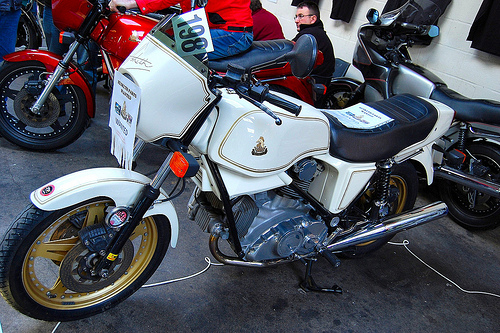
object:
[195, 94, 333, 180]
bars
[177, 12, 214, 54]
number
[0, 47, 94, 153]
wheel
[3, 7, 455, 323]
bike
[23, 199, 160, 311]
gold rim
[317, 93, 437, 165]
seat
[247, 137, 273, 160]
logo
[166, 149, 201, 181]
signal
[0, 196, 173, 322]
black tire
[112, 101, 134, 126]
graphic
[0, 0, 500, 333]
table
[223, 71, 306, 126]
handlebar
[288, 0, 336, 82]
man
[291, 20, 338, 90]
jacket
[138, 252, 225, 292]
cord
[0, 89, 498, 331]
ground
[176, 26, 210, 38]
9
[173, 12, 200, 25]
1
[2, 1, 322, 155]
motorcycle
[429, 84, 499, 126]
seat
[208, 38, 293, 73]
seat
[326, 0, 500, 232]
bike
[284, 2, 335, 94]
glasses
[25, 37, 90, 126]
fender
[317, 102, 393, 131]
note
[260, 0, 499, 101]
wall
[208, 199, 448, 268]
exhaust pipe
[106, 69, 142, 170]
sign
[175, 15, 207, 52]
198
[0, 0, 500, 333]
parking lot